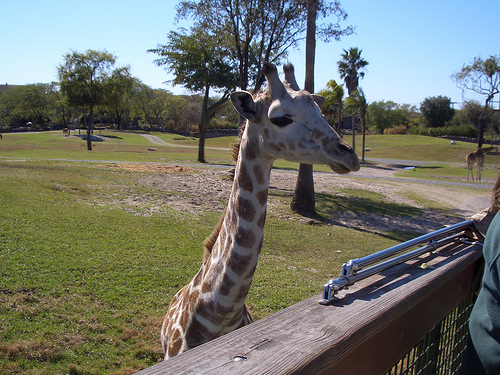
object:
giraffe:
[464, 145, 497, 184]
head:
[230, 61, 359, 175]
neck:
[199, 157, 273, 302]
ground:
[419, 184, 439, 224]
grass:
[0, 125, 499, 373]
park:
[0, 0, 499, 375]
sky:
[0, 0, 499, 113]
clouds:
[419, 81, 481, 108]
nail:
[230, 354, 251, 362]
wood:
[112, 197, 495, 374]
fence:
[121, 207, 500, 374]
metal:
[320, 217, 476, 307]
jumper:
[467, 183, 500, 375]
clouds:
[360, 88, 401, 107]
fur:
[158, 122, 278, 361]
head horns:
[263, 62, 300, 93]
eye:
[268, 113, 293, 127]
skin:
[161, 83, 334, 363]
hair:
[223, 121, 247, 184]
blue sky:
[0, 0, 499, 115]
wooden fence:
[403, 237, 479, 327]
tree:
[48, 46, 141, 152]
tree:
[148, 0, 357, 162]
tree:
[284, 0, 332, 214]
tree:
[448, 53, 500, 147]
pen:
[3, 124, 500, 374]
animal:
[160, 61, 361, 363]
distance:
[0, 48, 235, 164]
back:
[160, 201, 251, 303]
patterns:
[206, 243, 249, 316]